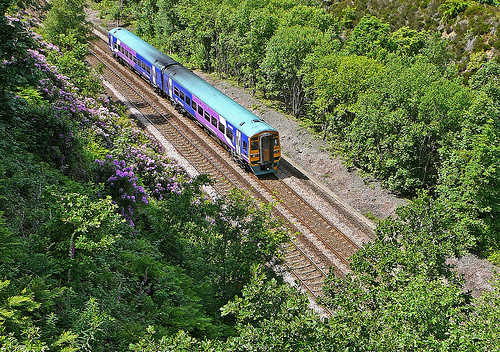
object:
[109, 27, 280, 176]
train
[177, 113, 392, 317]
tracks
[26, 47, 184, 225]
flower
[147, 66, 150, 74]
windows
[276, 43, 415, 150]
trees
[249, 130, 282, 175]
front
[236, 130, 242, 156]
doors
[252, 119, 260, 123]
marks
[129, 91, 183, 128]
shadow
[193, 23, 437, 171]
wilderness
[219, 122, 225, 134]
window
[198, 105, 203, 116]
glass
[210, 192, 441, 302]
ground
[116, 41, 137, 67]
purple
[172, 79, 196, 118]
blue